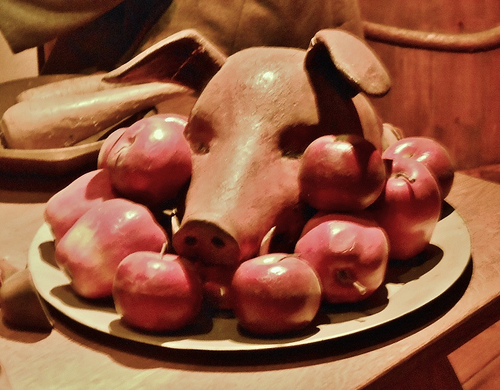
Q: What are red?
A: Apples.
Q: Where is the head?
A: On the plate.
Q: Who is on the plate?
A: A pig head.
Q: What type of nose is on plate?
A: A snort.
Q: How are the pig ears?
A: Down.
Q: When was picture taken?
A: Daytime.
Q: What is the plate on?
A: Table.